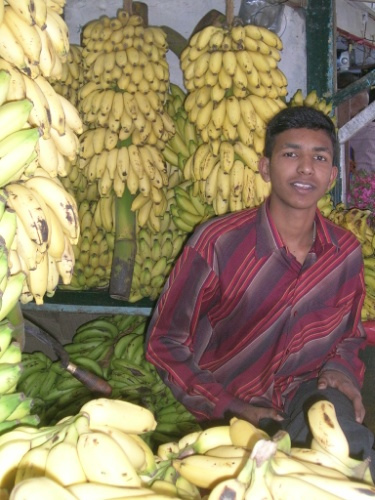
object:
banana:
[306, 400, 348, 457]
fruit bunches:
[82, 27, 277, 180]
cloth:
[276, 377, 371, 463]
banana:
[129, 140, 144, 180]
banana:
[194, 83, 210, 108]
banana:
[249, 47, 268, 74]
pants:
[286, 383, 375, 457]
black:
[278, 375, 374, 459]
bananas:
[0, 398, 374, 499]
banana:
[21, 71, 56, 141]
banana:
[220, 92, 244, 128]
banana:
[248, 93, 275, 121]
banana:
[201, 160, 220, 203]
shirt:
[149, 207, 363, 410]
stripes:
[148, 206, 369, 410]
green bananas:
[69, 323, 152, 395]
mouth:
[287, 178, 317, 196]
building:
[0, 0, 374, 492]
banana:
[145, 56, 160, 86]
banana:
[128, 85, 150, 115]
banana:
[101, 118, 119, 152]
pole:
[108, 182, 136, 301]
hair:
[265, 106, 340, 165]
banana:
[138, 235, 154, 260]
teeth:
[291, 180, 316, 191]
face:
[272, 131, 330, 207]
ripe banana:
[207, 477, 243, 498]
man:
[146, 105, 372, 462]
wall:
[0, 0, 375, 500]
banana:
[74, 399, 159, 440]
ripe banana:
[53, 391, 192, 499]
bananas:
[77, 5, 169, 302]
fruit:
[305, 396, 350, 458]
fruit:
[79, 396, 157, 434]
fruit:
[170, 451, 248, 489]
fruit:
[23, 176, 78, 239]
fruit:
[127, 143, 144, 178]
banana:
[29, 173, 86, 242]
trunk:
[101, 191, 139, 306]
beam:
[108, 2, 139, 297]